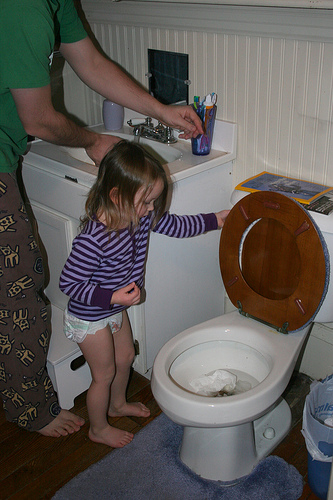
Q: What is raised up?
A: Toilet seat.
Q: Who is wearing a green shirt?
A: Adult.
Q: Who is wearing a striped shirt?
A: Child.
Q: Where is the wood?
A: Toilet seat.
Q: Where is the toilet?
A: Bathroom.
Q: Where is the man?
A: Beside girl.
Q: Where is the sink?
A: Bathroom.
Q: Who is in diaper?
A: Little girl.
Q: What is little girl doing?
A: Flushing toilet.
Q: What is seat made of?
A: Wood.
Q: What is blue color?
A: Rug.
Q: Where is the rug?
A: On floor.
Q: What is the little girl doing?
A: The little girl is flushing a toilet.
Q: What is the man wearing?
A: The man is wearing a green shirt.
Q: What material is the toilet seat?
A: It is a wooden toilet seat.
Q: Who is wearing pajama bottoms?
A: A man is wearing pajama bottoms.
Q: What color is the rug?
A: Blue.